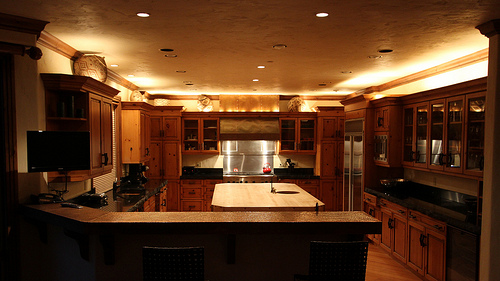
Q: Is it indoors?
A: Yes, it is indoors.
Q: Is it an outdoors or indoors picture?
A: It is indoors.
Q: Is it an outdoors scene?
A: No, it is indoors.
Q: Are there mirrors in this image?
A: No, there are no mirrors.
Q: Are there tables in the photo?
A: Yes, there is a table.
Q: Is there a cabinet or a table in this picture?
A: Yes, there is a table.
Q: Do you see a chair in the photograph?
A: Yes, there is a chair.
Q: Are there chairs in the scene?
A: Yes, there is a chair.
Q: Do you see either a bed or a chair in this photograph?
A: Yes, there is a chair.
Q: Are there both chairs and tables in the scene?
A: Yes, there are both a chair and a table.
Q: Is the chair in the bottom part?
A: Yes, the chair is in the bottom of the image.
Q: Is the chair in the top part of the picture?
A: No, the chair is in the bottom of the image.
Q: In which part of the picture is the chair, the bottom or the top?
A: The chair is in the bottom of the image.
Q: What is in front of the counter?
A: The chair is in front of the counter.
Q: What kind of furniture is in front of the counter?
A: The piece of furniture is a chair.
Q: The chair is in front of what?
A: The chair is in front of the counter.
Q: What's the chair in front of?
A: The chair is in front of the counter.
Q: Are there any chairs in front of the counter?
A: Yes, there is a chair in front of the counter.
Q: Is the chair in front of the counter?
A: Yes, the chair is in front of the counter.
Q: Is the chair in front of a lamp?
A: No, the chair is in front of the counter.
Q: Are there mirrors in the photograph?
A: No, there are no mirrors.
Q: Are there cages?
A: No, there are no cages.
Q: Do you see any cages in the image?
A: No, there are no cages.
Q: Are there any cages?
A: No, there are no cages.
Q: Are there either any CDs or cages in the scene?
A: No, there are no cages or cds.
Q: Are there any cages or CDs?
A: No, there are no cages or cds.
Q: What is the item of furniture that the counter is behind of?
A: The piece of furniture is a chair.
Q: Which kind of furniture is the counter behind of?
A: The counter is behind the chair.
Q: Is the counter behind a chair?
A: Yes, the counter is behind a chair.